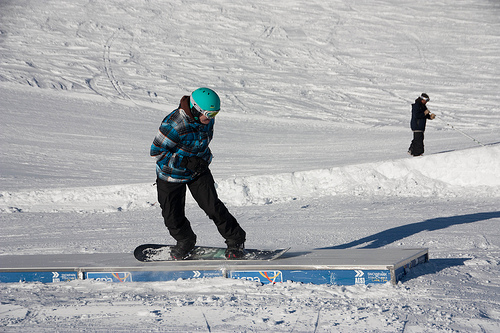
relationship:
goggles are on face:
[202, 108, 219, 120] [199, 111, 216, 125]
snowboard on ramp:
[132, 242, 291, 261] [0, 246, 430, 286]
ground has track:
[0, 0, 500, 333] [102, 27, 135, 105]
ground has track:
[0, 0, 500, 333] [251, 25, 279, 64]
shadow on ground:
[313, 211, 500, 249] [0, 0, 500, 333]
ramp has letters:
[0, 246, 430, 286] [354, 277, 365, 285]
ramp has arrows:
[0, 246, 430, 286] [352, 269, 364, 279]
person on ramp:
[148, 86, 247, 258] [0, 246, 430, 286]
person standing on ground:
[409, 92, 437, 158] [0, 0, 500, 333]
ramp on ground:
[0, 246, 430, 286] [0, 0, 500, 333]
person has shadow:
[148, 86, 247, 258] [313, 211, 500, 249]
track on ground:
[102, 27, 135, 105] [0, 0, 500, 333]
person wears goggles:
[148, 86, 247, 258] [202, 108, 219, 120]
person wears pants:
[148, 86, 247, 258] [154, 169, 247, 244]